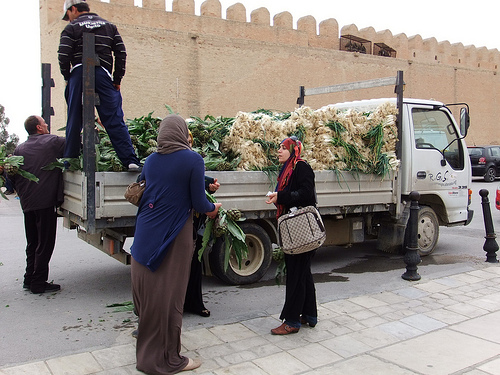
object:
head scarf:
[276, 136, 308, 216]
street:
[0, 181, 500, 375]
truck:
[58, 72, 474, 276]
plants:
[313, 134, 364, 157]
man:
[57, 0, 137, 172]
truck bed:
[61, 105, 396, 227]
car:
[470, 146, 499, 183]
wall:
[0, 0, 500, 146]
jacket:
[16, 135, 63, 209]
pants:
[19, 207, 59, 286]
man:
[10, 113, 68, 293]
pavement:
[12, 262, 499, 375]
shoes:
[27, 283, 65, 294]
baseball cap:
[60, 0, 90, 21]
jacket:
[56, 14, 127, 86]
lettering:
[78, 21, 85, 27]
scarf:
[157, 114, 197, 155]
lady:
[131, 112, 211, 373]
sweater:
[130, 150, 212, 263]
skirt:
[134, 217, 190, 372]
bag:
[275, 203, 327, 257]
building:
[0, 2, 500, 155]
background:
[5, 0, 499, 112]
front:
[339, 95, 476, 257]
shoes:
[269, 321, 300, 336]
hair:
[23, 115, 39, 134]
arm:
[264, 166, 315, 206]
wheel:
[404, 204, 443, 258]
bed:
[64, 151, 128, 187]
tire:
[207, 221, 275, 284]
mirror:
[457, 106, 470, 137]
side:
[398, 87, 488, 228]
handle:
[416, 171, 427, 179]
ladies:
[266, 136, 314, 338]